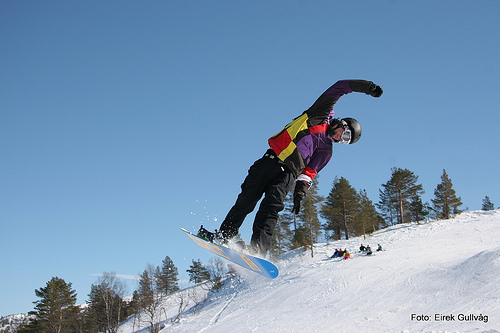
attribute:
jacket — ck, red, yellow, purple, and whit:
[266, 106, 346, 185]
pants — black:
[197, 142, 293, 259]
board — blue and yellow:
[187, 224, 288, 295]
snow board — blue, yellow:
[169, 220, 279, 283]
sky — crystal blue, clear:
[3, 1, 490, 311]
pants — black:
[204, 159, 439, 297]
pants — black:
[220, 142, 300, 258]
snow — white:
[96, 207, 498, 331]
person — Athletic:
[217, 70, 383, 255]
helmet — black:
[343, 109, 366, 149]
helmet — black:
[342, 117, 362, 143]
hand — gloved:
[292, 193, 304, 211]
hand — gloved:
[369, 86, 382, 95]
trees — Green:
[326, 166, 493, 229]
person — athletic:
[198, 78, 383, 258]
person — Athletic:
[198, 74, 383, 279]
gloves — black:
[347, 61, 381, 117]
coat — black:
[223, 78, 379, 250]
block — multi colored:
[269, 133, 297, 157]